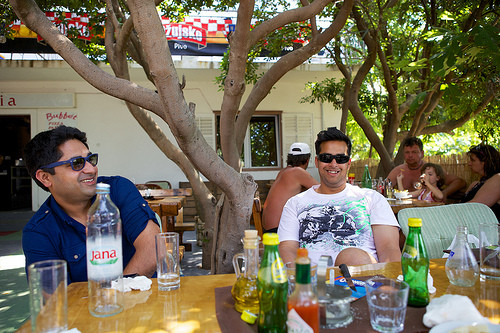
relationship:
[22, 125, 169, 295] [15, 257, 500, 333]
man around table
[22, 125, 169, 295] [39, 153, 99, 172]
man wearing sunglasses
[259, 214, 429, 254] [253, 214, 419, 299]
caps of bottles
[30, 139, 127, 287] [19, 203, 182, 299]
man wearing shirt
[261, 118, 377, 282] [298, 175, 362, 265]
man wearing shirt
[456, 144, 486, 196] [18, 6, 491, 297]
woman in background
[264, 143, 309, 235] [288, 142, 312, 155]
man wearing cap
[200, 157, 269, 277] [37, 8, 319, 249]
trunk of tree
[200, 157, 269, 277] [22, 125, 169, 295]
trunk between man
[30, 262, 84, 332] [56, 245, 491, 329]
glass on table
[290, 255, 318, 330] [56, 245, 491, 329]
bottle on table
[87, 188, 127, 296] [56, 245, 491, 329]
bottle on table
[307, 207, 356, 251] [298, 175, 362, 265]
design on shirt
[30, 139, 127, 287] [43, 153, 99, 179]
man in sunglasses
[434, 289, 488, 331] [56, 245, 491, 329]
napkin on table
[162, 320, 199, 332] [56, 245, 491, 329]
sun shining on table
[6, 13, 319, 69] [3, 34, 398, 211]
sign on building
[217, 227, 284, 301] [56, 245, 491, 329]
bottle on table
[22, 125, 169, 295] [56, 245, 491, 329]
man at table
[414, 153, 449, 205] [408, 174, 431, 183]
child has glass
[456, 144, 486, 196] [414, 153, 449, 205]
woman next to child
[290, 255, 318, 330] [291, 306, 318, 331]
bottle of hot suace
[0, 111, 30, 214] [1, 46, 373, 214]
entryway into restaurant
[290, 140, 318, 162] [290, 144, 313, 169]
cap on head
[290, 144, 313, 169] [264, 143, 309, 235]
head of man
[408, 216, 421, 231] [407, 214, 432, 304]
cap of bottle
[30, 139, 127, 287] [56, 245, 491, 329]
man at table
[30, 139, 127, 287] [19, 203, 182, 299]
man with shirt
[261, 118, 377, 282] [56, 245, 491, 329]
man at table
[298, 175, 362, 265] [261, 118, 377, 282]
shirt on man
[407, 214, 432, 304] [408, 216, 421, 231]
bottle has cap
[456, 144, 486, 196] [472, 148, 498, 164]
woman wearing sunglasses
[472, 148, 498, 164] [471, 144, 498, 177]
sunglasses on head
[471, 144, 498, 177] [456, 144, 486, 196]
head of woman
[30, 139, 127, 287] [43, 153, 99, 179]
man wearing sunglasses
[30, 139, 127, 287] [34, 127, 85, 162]
man with hair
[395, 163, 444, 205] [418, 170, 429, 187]
child with can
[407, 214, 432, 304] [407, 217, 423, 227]
bottle with cap